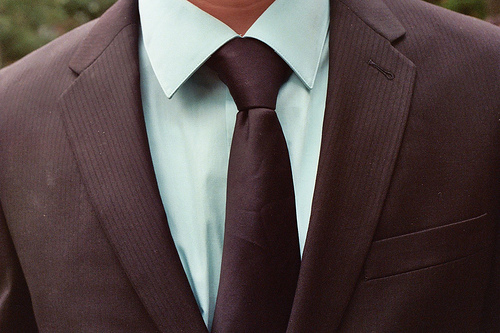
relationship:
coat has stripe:
[0, 0, 499, 331] [329, 44, 397, 314]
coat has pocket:
[0, 0, 499, 331] [363, 209, 491, 333]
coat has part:
[0, 0, 499, 331] [364, 53, 395, 85]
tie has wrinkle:
[208, 39, 301, 332] [231, 228, 265, 256]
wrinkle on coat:
[3, 268, 16, 310] [0, 0, 499, 331]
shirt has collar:
[135, 1, 331, 333] [136, 1, 333, 101]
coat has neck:
[0, 0, 499, 331] [189, 1, 276, 35]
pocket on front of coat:
[363, 209, 491, 333] [0, 0, 499, 331]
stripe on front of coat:
[329, 44, 397, 314] [0, 0, 499, 331]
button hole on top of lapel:
[363, 50, 401, 84] [283, 2, 420, 332]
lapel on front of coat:
[283, 2, 420, 332] [0, 0, 499, 331]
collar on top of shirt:
[136, 1, 333, 101] [135, 1, 331, 333]